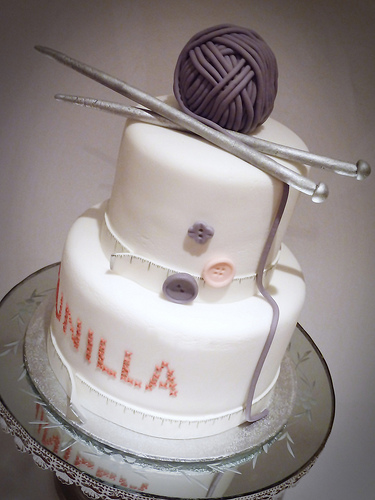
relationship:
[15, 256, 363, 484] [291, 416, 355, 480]
plate for serving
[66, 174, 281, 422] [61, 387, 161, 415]
themed cake for an occasion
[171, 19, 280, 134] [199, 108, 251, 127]
ball of yarn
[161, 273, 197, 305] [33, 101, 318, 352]
button on sculpture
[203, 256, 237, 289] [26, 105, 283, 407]
button on sculpture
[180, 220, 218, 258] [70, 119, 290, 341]
button on sculpture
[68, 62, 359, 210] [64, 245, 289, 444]
knitting needle on sculpture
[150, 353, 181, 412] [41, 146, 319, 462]
letter on sculpure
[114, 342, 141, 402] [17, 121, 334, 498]
letter on sculpure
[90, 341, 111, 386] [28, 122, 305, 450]
letter on sculpure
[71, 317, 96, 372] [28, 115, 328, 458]
letter on sculpure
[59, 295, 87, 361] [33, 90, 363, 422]
letter on sculpure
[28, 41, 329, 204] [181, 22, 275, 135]
nail next to ball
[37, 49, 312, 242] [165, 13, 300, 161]
nail next to ball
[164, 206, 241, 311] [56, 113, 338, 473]
button on cake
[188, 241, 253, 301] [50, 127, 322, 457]
button on cake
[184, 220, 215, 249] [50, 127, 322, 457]
button on cake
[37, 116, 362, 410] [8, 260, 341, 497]
cake on plate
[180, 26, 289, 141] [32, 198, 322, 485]
ball on cake